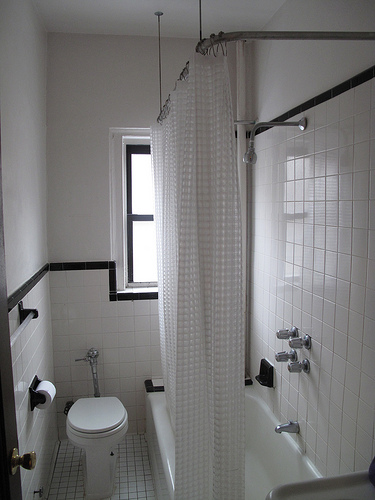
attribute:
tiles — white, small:
[134, 473, 142, 486]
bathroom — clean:
[7, 13, 360, 486]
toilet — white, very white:
[67, 399, 136, 461]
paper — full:
[36, 380, 57, 403]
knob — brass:
[14, 453, 37, 474]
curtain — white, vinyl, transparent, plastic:
[138, 109, 257, 379]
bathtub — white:
[152, 394, 282, 499]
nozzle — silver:
[272, 417, 301, 440]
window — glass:
[111, 129, 162, 296]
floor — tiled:
[50, 436, 151, 497]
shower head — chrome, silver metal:
[243, 117, 264, 174]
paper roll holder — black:
[30, 375, 40, 415]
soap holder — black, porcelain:
[254, 361, 277, 390]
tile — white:
[62, 281, 95, 313]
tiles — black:
[51, 262, 115, 271]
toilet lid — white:
[72, 399, 125, 431]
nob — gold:
[14, 448, 48, 477]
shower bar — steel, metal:
[239, 111, 321, 163]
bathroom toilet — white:
[67, 386, 129, 483]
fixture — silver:
[275, 327, 289, 340]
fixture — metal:
[285, 335, 310, 347]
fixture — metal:
[275, 348, 289, 365]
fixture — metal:
[288, 359, 310, 380]